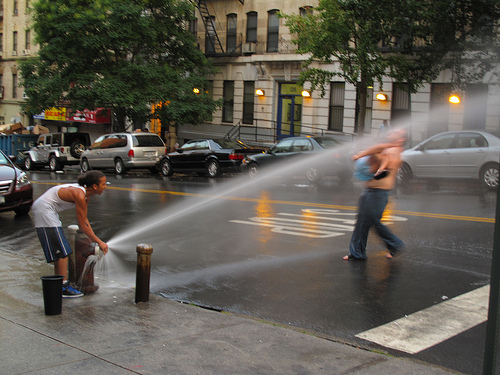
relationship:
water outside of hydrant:
[78, 98, 499, 294] [75, 229, 98, 293]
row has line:
[0, 163, 499, 374] [355, 284, 498, 353]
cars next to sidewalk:
[0, 149, 35, 217] [1, 246, 464, 374]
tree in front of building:
[17, 0, 225, 132] [0, 0, 499, 152]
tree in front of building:
[276, 0, 499, 134] [0, 0, 499, 152]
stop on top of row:
[229, 208, 408, 239] [0, 163, 499, 374]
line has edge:
[355, 284, 498, 353] [354, 332, 417, 353]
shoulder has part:
[74, 189, 86, 202] [79, 193, 84, 199]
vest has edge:
[29, 182, 86, 226] [35, 222, 62, 227]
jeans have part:
[350, 188, 405, 261] [353, 227, 364, 258]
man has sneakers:
[31, 170, 106, 298] [61, 282, 83, 297]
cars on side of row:
[0, 149, 35, 217] [0, 163, 499, 374]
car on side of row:
[81, 133, 166, 173] [0, 163, 499, 374]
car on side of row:
[24, 132, 90, 170] [0, 163, 499, 374]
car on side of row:
[155, 138, 264, 176] [0, 163, 499, 374]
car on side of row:
[241, 136, 354, 181] [0, 163, 499, 374]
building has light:
[0, 0, 499, 152] [255, 90, 263, 95]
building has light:
[0, 0, 499, 152] [302, 88, 308, 96]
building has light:
[0, 0, 499, 152] [377, 95, 387, 100]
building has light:
[0, 0, 499, 152] [448, 97, 458, 102]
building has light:
[0, 0, 499, 152] [194, 87, 199, 93]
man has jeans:
[342, 128, 409, 260] [350, 188, 405, 261]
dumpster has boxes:
[0, 136, 37, 160] [1, 121, 51, 135]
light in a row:
[194, 87, 199, 93] [191, 87, 461, 103]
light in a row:
[302, 88, 308, 96] [191, 87, 461, 103]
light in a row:
[377, 95, 387, 100] [191, 87, 461, 103]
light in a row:
[448, 97, 458, 102] [191, 87, 461, 103]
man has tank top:
[31, 170, 106, 298] [29, 182, 86, 226]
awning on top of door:
[252, 54, 313, 81] [277, 81, 302, 138]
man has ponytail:
[31, 170, 106, 298] [78, 177, 86, 186]